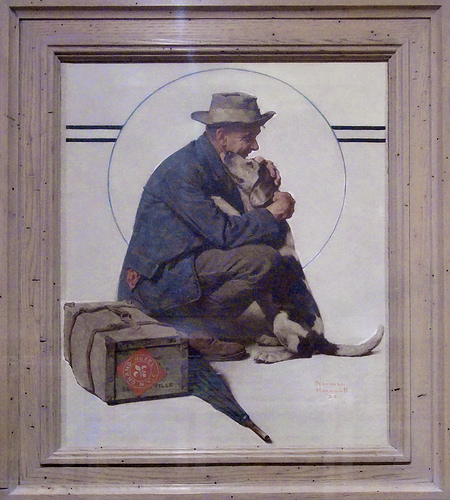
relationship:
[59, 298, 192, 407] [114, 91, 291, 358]
case by man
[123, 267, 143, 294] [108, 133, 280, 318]
rag in jacket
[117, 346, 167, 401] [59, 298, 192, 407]
sticker on case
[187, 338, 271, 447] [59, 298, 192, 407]
umbrella by case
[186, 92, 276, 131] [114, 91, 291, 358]
hat on man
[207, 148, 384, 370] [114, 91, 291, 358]
dog on man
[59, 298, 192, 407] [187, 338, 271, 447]
case by umbrella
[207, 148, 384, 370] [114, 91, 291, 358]
dog near man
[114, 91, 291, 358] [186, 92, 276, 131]
man with hat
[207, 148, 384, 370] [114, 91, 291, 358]
dog and h man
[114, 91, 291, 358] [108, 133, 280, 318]
man wearing a blue jacket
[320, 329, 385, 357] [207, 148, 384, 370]
tail on dog